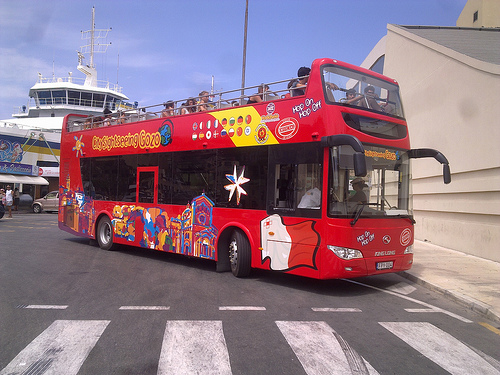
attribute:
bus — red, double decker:
[55, 55, 453, 282]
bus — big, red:
[54, 88, 427, 275]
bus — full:
[56, 53, 416, 279]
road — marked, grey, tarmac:
[117, 283, 468, 349]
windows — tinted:
[82, 145, 269, 207]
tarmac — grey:
[40, 232, 161, 316]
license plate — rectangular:
[376, 257, 396, 271]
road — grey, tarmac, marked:
[1, 216, 494, 373]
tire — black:
[92, 212, 117, 250]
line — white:
[154, 314, 226, 374]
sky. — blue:
[8, 4, 438, 26]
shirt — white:
[2, 187, 14, 204]